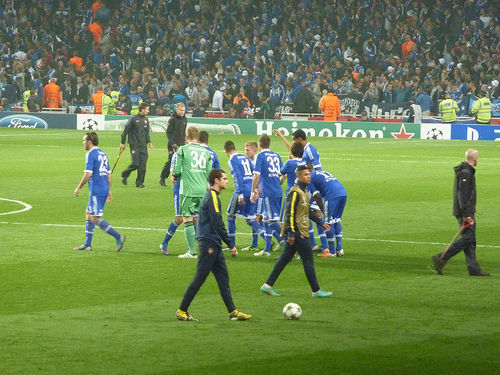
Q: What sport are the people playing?
A: Soccer.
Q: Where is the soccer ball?
A: On the field.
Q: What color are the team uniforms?
A: Blue and green.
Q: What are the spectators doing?
A: Watching the game.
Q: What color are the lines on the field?
A: White.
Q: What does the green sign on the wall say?
A: Heineken.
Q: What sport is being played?
A: Soccer.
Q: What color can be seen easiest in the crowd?
A: Orange.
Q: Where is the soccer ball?
A: Grass.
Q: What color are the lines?
A: White.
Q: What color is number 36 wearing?
A: Green.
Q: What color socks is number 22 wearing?
A: Blue.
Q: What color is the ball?
A: Black and white.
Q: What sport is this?
A: Soccer.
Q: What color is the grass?
A: Green.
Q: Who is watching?
A: Fans.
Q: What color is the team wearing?
A: Blue.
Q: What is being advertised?
A: Heineken.